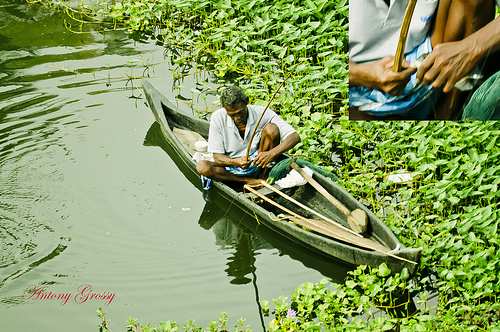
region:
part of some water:
[134, 265, 175, 310]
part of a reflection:
[230, 256, 266, 299]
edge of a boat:
[302, 215, 340, 264]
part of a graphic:
[60, 271, 121, 313]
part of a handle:
[275, 185, 298, 230]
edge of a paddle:
[351, 210, 373, 233]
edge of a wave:
[43, 213, 98, 272]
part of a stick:
[246, 275, 263, 295]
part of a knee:
[193, 155, 211, 176]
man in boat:
[190, 83, 318, 192]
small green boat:
[143, 77, 425, 277]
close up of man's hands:
[352, 37, 477, 99]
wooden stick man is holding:
[236, 52, 311, 162]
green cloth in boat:
[263, 154, 330, 180]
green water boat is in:
[3, 6, 355, 320]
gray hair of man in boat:
[217, 87, 257, 110]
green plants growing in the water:
[107, 0, 499, 322]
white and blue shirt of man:
[206, 106, 298, 172]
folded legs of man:
[205, 133, 286, 188]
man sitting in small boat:
[205, 78, 296, 191]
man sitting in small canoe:
[128, 82, 415, 274]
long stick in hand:
[384, 5, 424, 67]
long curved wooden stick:
[394, 2, 417, 68]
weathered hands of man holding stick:
[367, 38, 482, 98]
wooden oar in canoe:
[292, 163, 364, 234]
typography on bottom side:
[22, 274, 125, 321]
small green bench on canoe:
[249, 165, 304, 199]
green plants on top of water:
[236, 283, 401, 330]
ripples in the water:
[12, 13, 146, 160]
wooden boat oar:
[290, 157, 370, 233]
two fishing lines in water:
[217, 190, 250, 247]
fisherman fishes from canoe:
[136, 71, 420, 278]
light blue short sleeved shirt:
[208, 104, 293, 154]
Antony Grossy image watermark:
[20, 283, 117, 308]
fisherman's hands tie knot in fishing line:
[372, 42, 477, 97]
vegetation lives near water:
[139, 10, 318, 62]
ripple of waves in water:
[7, 47, 61, 164]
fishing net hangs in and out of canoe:
[265, 153, 336, 183]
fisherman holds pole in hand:
[238, 57, 302, 169]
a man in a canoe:
[127, 67, 431, 289]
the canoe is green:
[120, 55, 431, 290]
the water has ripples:
[1, 31, 203, 186]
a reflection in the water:
[190, 171, 291, 330]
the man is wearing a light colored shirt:
[198, 87, 307, 210]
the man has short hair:
[177, 74, 320, 221]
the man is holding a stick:
[189, 55, 306, 213]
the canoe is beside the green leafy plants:
[118, 18, 496, 330]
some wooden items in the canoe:
[240, 156, 420, 289]